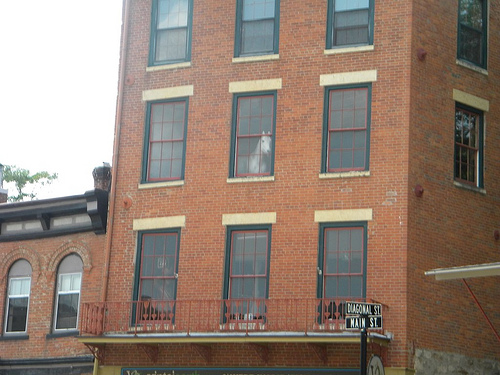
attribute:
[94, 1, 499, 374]
building — tall, brick, brown, large, red, tall'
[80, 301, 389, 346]
balcony — brown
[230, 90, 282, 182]
window — tall, green, red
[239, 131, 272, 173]
horse — white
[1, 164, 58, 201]
trees — here, green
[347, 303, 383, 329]
words — white, black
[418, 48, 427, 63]
siren — red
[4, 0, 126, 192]
sky — pale